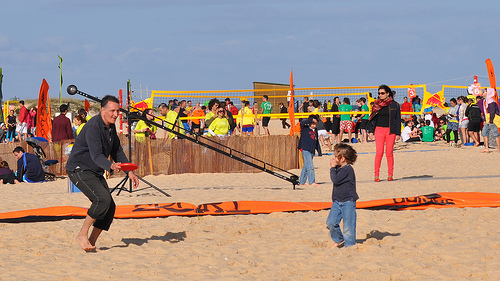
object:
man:
[63, 95, 139, 250]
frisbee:
[118, 162, 139, 171]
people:
[368, 85, 401, 182]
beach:
[414, 148, 459, 171]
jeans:
[298, 150, 315, 185]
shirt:
[420, 125, 435, 141]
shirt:
[236, 107, 256, 126]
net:
[152, 87, 424, 116]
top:
[399, 84, 425, 88]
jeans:
[325, 197, 356, 247]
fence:
[0, 134, 300, 180]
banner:
[36, 78, 53, 143]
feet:
[75, 235, 96, 251]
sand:
[175, 236, 296, 276]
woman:
[456, 95, 470, 145]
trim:
[413, 84, 427, 114]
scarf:
[368, 96, 394, 122]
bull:
[426, 96, 445, 109]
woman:
[367, 85, 401, 183]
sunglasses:
[378, 92, 389, 95]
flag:
[485, 58, 500, 107]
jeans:
[374, 126, 396, 177]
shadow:
[97, 230, 186, 250]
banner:
[0, 192, 499, 221]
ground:
[156, 232, 268, 265]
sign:
[288, 69, 301, 136]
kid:
[325, 143, 360, 248]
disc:
[99, 141, 142, 171]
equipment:
[65, 81, 299, 190]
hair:
[101, 95, 120, 108]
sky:
[68, 28, 331, 80]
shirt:
[65, 112, 133, 176]